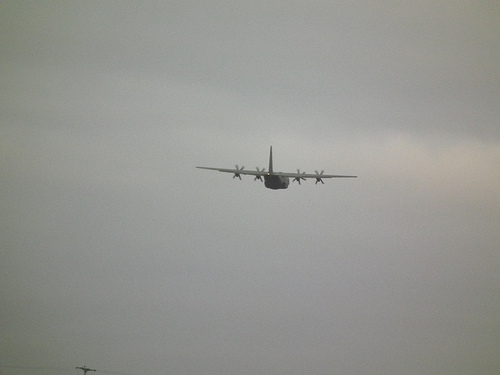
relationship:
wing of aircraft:
[193, 159, 268, 181] [196, 144, 359, 192]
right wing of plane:
[285, 167, 367, 186] [193, 143, 357, 190]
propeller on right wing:
[292, 167, 308, 186] [285, 170, 359, 185]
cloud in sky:
[358, 123, 498, 187] [1, 2, 496, 370]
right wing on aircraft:
[285, 170, 359, 185] [196, 144, 359, 192]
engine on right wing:
[314, 169, 325, 186] [285, 170, 359, 185]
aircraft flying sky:
[196, 144, 359, 192] [1, 2, 496, 370]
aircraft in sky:
[196, 144, 358, 193] [1, 2, 496, 370]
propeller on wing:
[251, 167, 267, 182] [195, 159, 267, 178]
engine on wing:
[314, 171, 324, 184] [270, 165, 360, 186]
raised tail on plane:
[264, 141, 282, 176] [134, 70, 496, 298]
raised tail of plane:
[267, 146, 275, 172] [194, 146, 356, 188]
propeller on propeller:
[232, 163, 244, 181] [252, 165, 264, 182]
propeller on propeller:
[232, 163, 244, 181] [290, 168, 306, 185]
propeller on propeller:
[232, 163, 244, 181] [312, 169, 325, 184]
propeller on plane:
[232, 163, 244, 181] [193, 143, 357, 190]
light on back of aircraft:
[253, 164, 275, 188] [196, 144, 359, 192]